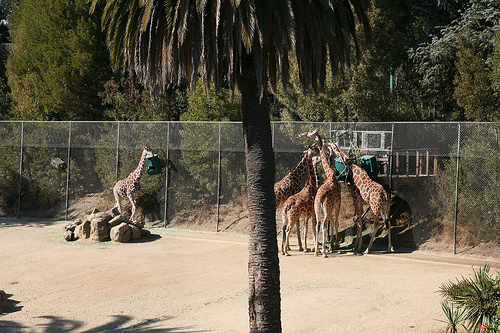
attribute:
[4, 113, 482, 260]
fence — thick, tall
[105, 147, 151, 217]
giraffe — lone, lonely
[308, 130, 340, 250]
giraffe — largest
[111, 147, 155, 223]
giraffe — small, lone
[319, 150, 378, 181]
food bin — dark teal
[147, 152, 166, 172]
food bin — dark teal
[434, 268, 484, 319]
plant — leafy, frizzy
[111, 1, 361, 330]
palm tree — large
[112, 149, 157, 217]
giraffe — lonely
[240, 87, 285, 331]
tree trunk — brown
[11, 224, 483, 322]
dirt — tan, sandy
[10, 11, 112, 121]
tree top — green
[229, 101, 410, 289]
giraffes — huddled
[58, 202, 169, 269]
rocks — grouped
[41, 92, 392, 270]
giraffes — metal, large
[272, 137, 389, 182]
necks — reaching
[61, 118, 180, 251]
giraffe — alone, away from others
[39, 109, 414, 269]
animals — group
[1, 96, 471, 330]
area — enclosed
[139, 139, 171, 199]
basket — green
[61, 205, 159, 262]
rocks — large pile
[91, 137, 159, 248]
giraffe — broiwn, white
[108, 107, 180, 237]
giraffe — long necked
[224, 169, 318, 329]
trunk — grayish brown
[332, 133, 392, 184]
bucket — green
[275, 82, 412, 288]
giraffe — brown, white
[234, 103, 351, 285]
giraffe — white, brown